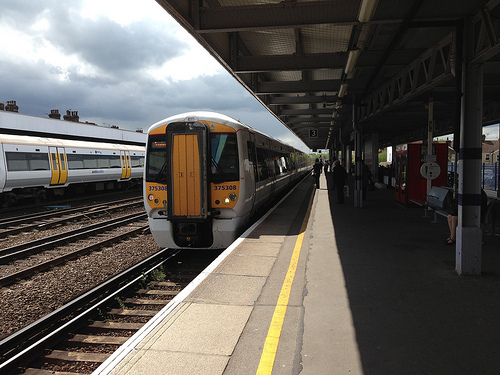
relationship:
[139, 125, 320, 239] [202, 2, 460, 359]
train near platform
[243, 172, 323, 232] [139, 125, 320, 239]
shadow near train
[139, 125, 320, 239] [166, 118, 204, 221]
train has doors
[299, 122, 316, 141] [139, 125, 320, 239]
sign above train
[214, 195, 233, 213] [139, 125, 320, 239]
light on back of train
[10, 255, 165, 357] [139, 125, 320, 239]
tracks beneath train